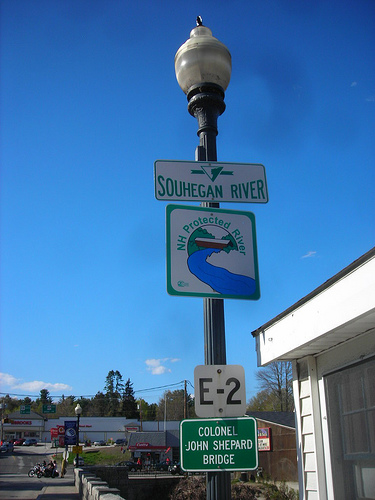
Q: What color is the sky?
A: Blue.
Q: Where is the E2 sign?
A: On pole.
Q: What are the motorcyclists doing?
A: Riding.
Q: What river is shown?
A: Souhegan.